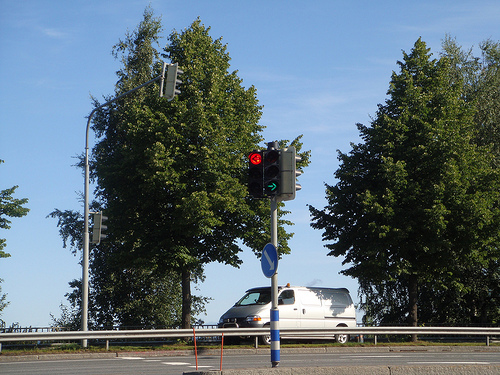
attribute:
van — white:
[218, 286, 358, 341]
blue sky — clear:
[1, 0, 498, 331]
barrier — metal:
[5, 316, 493, 338]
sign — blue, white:
[259, 241, 279, 276]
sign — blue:
[259, 239, 281, 279]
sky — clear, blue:
[252, 32, 329, 102]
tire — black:
[261, 323, 275, 344]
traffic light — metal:
[159, 60, 178, 99]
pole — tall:
[78, 85, 153, 352]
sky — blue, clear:
[6, 4, 480, 184]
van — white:
[216, 283, 358, 347]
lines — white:
[144, 315, 496, 365]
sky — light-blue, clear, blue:
[1, 0, 499, 323]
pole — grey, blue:
[253, 209, 283, 235]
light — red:
[216, 130, 334, 211]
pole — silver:
[63, 105, 120, 352]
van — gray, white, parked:
[211, 277, 358, 345]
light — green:
[263, 150, 278, 195]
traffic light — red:
[246, 150, 263, 167]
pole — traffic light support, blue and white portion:
[268, 205, 281, 369]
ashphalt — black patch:
[18, 348, 369, 373]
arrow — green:
[264, 182, 277, 192]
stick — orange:
[189, 321, 202, 373]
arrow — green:
[262, 173, 277, 196]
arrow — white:
[253, 234, 291, 279]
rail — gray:
[4, 323, 498, 352]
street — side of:
[11, 327, 488, 365]